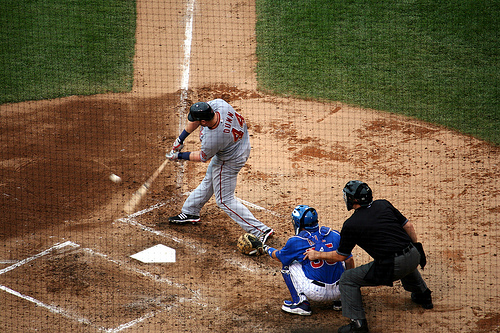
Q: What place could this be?
A: It is a field.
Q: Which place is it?
A: It is a field.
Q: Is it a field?
A: Yes, it is a field.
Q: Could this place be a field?
A: Yes, it is a field.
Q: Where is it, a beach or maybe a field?
A: It is a field.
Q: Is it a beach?
A: No, it is a field.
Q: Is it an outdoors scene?
A: Yes, it is outdoors.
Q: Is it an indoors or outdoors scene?
A: It is outdoors.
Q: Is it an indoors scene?
A: No, it is outdoors.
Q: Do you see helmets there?
A: Yes, there is a helmet.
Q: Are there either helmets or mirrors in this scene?
A: Yes, there is a helmet.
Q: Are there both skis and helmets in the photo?
A: No, there is a helmet but no skis.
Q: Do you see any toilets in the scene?
A: No, there are no toilets.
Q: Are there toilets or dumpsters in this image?
A: No, there are no toilets or dumpsters.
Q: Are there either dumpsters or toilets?
A: No, there are no toilets or dumpsters.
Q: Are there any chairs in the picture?
A: No, there are no chairs.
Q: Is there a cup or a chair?
A: No, there are no chairs or cups.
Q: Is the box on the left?
A: Yes, the box is on the left of the image.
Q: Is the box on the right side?
A: No, the box is on the left of the image.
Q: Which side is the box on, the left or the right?
A: The box is on the left of the image.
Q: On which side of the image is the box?
A: The box is on the left of the image.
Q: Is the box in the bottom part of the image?
A: Yes, the box is in the bottom of the image.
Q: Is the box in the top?
A: No, the box is in the bottom of the image.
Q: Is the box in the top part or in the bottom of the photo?
A: The box is in the bottom of the image.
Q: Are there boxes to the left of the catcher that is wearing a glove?
A: Yes, there is a box to the left of the catcher.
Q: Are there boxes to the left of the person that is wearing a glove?
A: Yes, there is a box to the left of the catcher.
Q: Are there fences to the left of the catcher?
A: No, there is a box to the left of the catcher.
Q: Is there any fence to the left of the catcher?
A: No, there is a box to the left of the catcher.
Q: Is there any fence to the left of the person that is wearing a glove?
A: No, there is a box to the left of the catcher.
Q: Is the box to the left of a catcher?
A: Yes, the box is to the left of a catcher.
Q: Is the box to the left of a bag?
A: No, the box is to the left of a catcher.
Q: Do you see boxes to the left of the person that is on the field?
A: Yes, there is a box to the left of the person.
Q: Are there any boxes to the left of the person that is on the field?
A: Yes, there is a box to the left of the person.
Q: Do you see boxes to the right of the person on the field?
A: No, the box is to the left of the person.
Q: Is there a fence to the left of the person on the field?
A: No, there is a box to the left of the person.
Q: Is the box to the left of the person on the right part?
A: Yes, the box is to the left of the person.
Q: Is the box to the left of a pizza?
A: No, the box is to the left of the person.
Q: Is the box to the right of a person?
A: No, the box is to the left of a person.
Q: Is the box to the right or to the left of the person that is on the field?
A: The box is to the left of the person.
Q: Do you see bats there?
A: Yes, there is a bat.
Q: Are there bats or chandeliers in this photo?
A: Yes, there is a bat.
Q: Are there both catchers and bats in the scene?
A: Yes, there are both a bat and a catcher.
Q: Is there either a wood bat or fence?
A: Yes, there is a wood bat.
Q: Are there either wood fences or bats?
A: Yes, there is a wood bat.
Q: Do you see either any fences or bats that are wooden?
A: Yes, the bat is wooden.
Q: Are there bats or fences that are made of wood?
A: Yes, the bat is made of wood.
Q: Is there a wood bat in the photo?
A: Yes, there is a wood bat.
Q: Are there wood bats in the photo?
A: Yes, there is a wood bat.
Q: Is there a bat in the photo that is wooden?
A: Yes, there is a bat that is wooden.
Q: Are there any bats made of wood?
A: Yes, there is a bat that is made of wood.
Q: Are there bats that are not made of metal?
A: Yes, there is a bat that is made of wood.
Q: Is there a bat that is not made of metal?
A: Yes, there is a bat that is made of wood.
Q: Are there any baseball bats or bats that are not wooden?
A: No, there is a bat but it is wooden.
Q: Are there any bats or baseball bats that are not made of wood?
A: No, there is a bat but it is made of wood.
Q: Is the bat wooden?
A: Yes, the bat is wooden.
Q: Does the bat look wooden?
A: Yes, the bat is wooden.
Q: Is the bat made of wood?
A: Yes, the bat is made of wood.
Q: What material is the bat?
A: The bat is made of wood.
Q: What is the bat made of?
A: The bat is made of wood.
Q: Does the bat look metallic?
A: No, the bat is wooden.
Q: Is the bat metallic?
A: No, the bat is wooden.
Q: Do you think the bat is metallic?
A: No, the bat is wooden.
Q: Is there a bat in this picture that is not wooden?
A: No, there is a bat but it is wooden.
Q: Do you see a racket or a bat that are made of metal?
A: No, there is a bat but it is made of wood.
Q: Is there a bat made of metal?
A: No, there is a bat but it is made of wood.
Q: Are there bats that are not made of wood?
A: No, there is a bat but it is made of wood.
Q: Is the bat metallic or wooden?
A: The bat is wooden.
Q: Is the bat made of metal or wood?
A: The bat is made of wood.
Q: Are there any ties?
A: No, there are no ties.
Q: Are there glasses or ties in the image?
A: No, there are no ties or glasses.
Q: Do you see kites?
A: No, there are no kites.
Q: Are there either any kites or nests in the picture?
A: No, there are no kites or nests.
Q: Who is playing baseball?
A: The man is playing baseball.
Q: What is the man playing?
A: The man is playing baseball.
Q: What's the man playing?
A: The man is playing baseball.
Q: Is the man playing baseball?
A: Yes, the man is playing baseball.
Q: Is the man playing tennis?
A: No, the man is playing baseball.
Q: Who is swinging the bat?
A: The man is swinging the bat.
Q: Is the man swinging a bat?
A: Yes, the man is swinging a bat.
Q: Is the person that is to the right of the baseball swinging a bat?
A: Yes, the man is swinging a bat.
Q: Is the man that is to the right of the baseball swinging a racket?
A: No, the man is swinging a bat.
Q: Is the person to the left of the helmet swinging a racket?
A: No, the man is swinging a bat.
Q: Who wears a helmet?
A: The man wears a helmet.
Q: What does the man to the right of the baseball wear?
A: The man wears a helmet.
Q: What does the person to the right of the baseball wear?
A: The man wears a helmet.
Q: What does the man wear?
A: The man wears a helmet.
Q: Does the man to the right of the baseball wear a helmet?
A: Yes, the man wears a helmet.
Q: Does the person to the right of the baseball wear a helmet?
A: Yes, the man wears a helmet.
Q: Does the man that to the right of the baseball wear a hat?
A: No, the man wears a helmet.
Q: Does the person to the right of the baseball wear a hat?
A: No, the man wears a helmet.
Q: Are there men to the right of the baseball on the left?
A: Yes, there is a man to the right of the baseball.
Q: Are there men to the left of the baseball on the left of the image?
A: No, the man is to the right of the baseball.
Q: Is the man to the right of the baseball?
A: Yes, the man is to the right of the baseball.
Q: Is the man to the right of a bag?
A: No, the man is to the right of the baseball.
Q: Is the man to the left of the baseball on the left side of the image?
A: No, the man is to the right of the baseball.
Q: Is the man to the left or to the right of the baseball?
A: The man is to the right of the baseball.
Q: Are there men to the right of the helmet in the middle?
A: No, the man is to the left of the helmet.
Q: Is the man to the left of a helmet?
A: Yes, the man is to the left of a helmet.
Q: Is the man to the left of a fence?
A: No, the man is to the left of a helmet.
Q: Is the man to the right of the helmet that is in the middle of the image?
A: No, the man is to the left of the helmet.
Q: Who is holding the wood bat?
A: The man is holding the bat.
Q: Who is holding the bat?
A: The man is holding the bat.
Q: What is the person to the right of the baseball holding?
A: The man is holding the bat.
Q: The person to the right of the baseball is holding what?
A: The man is holding the bat.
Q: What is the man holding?
A: The man is holding the bat.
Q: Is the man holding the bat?
A: Yes, the man is holding the bat.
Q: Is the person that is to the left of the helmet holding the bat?
A: Yes, the man is holding the bat.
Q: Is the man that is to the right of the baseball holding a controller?
A: No, the man is holding the bat.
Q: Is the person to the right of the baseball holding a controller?
A: No, the man is holding the bat.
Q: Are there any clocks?
A: No, there are no clocks.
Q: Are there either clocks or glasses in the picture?
A: No, there are no clocks or glasses.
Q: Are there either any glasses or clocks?
A: No, there are no clocks or glasses.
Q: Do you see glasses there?
A: No, there are no glasses.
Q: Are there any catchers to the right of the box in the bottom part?
A: Yes, there is a catcher to the right of the box.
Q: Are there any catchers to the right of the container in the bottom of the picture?
A: Yes, there is a catcher to the right of the box.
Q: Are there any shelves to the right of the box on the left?
A: No, there is a catcher to the right of the box.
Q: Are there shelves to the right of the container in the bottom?
A: No, there is a catcher to the right of the box.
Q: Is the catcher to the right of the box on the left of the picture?
A: Yes, the catcher is to the right of the box.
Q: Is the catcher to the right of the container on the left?
A: Yes, the catcher is to the right of the box.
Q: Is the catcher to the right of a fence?
A: No, the catcher is to the right of the box.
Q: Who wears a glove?
A: The catcher wears a glove.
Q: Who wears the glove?
A: The catcher wears a glove.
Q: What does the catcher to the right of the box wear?
A: The catcher wears a glove.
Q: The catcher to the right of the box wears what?
A: The catcher wears a glove.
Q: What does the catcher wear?
A: The catcher wears a glove.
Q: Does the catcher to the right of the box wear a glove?
A: Yes, the catcher wears a glove.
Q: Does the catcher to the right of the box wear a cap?
A: No, the catcher wears a glove.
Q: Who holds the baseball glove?
A: The catcher holds the glove.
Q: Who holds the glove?
A: The catcher holds the glove.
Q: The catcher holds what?
A: The catcher holds the glove.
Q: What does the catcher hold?
A: The catcher holds the glove.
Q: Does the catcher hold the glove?
A: Yes, the catcher holds the glove.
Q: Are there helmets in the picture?
A: Yes, there is a helmet.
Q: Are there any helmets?
A: Yes, there is a helmet.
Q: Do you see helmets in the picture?
A: Yes, there is a helmet.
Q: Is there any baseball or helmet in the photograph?
A: Yes, there is a helmet.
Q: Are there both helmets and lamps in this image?
A: No, there is a helmet but no lamps.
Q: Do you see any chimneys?
A: No, there are no chimneys.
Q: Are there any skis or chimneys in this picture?
A: No, there are no chimneys or skis.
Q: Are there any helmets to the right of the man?
A: Yes, there is a helmet to the right of the man.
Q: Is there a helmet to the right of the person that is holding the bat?
A: Yes, there is a helmet to the right of the man.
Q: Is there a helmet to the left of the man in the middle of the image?
A: No, the helmet is to the right of the man.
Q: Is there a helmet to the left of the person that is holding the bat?
A: No, the helmet is to the right of the man.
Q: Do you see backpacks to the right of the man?
A: No, there is a helmet to the right of the man.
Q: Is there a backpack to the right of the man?
A: No, there is a helmet to the right of the man.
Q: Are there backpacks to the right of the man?
A: No, there is a helmet to the right of the man.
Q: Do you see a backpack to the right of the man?
A: No, there is a helmet to the right of the man.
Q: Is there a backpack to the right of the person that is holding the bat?
A: No, there is a helmet to the right of the man.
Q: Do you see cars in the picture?
A: No, there are no cars.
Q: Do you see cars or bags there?
A: No, there are no cars or bags.